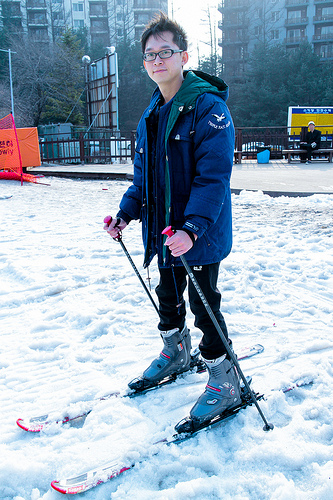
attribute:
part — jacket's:
[156, 67, 244, 268]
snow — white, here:
[3, 166, 332, 497]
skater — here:
[10, 18, 324, 492]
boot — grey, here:
[184, 347, 245, 425]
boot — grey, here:
[143, 328, 193, 385]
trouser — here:
[155, 257, 223, 356]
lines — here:
[7, 240, 330, 478]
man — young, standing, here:
[102, 8, 277, 433]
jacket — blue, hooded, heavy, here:
[114, 62, 247, 276]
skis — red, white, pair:
[11, 336, 320, 496]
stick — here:
[156, 222, 296, 440]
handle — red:
[158, 225, 176, 246]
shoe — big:
[191, 356, 246, 427]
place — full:
[3, 0, 330, 494]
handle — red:
[101, 214, 120, 232]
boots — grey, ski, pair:
[124, 346, 251, 425]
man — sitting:
[296, 118, 322, 162]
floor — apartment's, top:
[3, 0, 169, 19]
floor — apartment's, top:
[1, 10, 167, 37]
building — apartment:
[3, 3, 176, 132]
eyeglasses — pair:
[144, 43, 186, 64]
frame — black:
[143, 44, 188, 63]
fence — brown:
[40, 121, 332, 161]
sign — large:
[76, 51, 123, 139]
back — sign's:
[82, 53, 121, 141]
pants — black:
[149, 251, 230, 352]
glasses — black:
[143, 43, 188, 60]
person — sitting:
[299, 119, 320, 164]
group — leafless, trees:
[6, 21, 98, 135]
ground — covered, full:
[8, 144, 332, 493]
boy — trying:
[106, 12, 246, 426]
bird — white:
[213, 108, 229, 123]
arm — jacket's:
[179, 94, 239, 238]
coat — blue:
[116, 67, 254, 273]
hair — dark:
[142, 17, 193, 55]